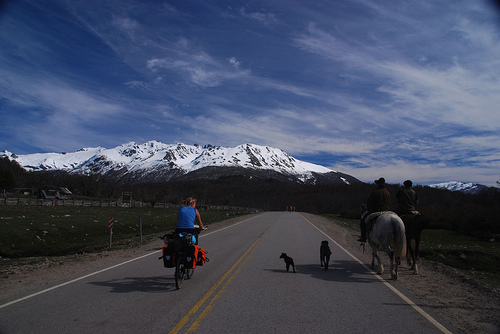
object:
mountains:
[148, 140, 309, 171]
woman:
[167, 193, 206, 233]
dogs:
[276, 251, 297, 273]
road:
[211, 211, 319, 243]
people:
[368, 171, 416, 208]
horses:
[399, 205, 429, 275]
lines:
[169, 233, 259, 334]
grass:
[70, 211, 105, 231]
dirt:
[76, 249, 100, 266]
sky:
[0, 0, 500, 138]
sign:
[107, 215, 118, 230]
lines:
[0, 255, 144, 310]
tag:
[186, 242, 215, 269]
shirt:
[172, 205, 199, 229]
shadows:
[328, 258, 383, 285]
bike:
[158, 227, 209, 290]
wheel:
[170, 259, 184, 290]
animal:
[403, 209, 428, 275]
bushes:
[450, 206, 477, 236]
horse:
[356, 204, 406, 282]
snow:
[106, 152, 127, 164]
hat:
[374, 177, 388, 185]